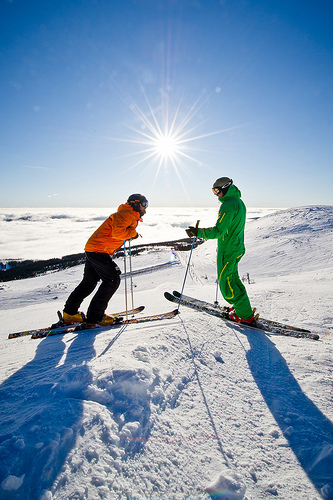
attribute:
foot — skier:
[220, 309, 255, 324]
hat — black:
[127, 183, 163, 210]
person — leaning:
[54, 194, 149, 329]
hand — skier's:
[162, 218, 216, 231]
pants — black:
[68, 249, 122, 326]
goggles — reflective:
[209, 178, 236, 196]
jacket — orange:
[84, 200, 145, 262]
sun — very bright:
[110, 80, 264, 216]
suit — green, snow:
[199, 185, 270, 329]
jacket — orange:
[85, 201, 141, 253]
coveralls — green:
[195, 186, 252, 318]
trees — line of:
[1, 254, 78, 281]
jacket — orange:
[82, 199, 146, 257]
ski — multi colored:
[31, 307, 177, 339]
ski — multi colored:
[7, 301, 144, 337]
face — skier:
[135, 194, 148, 214]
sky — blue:
[0, 2, 321, 195]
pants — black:
[61, 247, 124, 326]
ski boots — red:
[224, 303, 252, 325]